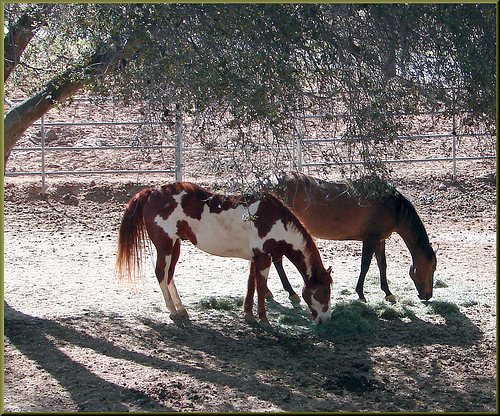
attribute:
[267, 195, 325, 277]
mane — Brown 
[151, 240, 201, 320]
legs — Back 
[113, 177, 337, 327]
horse — spotted , brown, white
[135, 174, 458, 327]
horse — brown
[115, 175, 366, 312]
horse — white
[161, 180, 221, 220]
spots — brown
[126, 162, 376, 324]
horse — spotted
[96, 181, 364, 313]
horse — spotted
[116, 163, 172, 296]
tail — brown, hairy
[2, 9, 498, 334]
tree — large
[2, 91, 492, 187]
fence — metal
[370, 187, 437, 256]
mane — dark colored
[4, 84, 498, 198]
fence — silver, metal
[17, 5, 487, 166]
leaves — green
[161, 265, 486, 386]
grass — green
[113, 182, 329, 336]
horse — brown, white, spotted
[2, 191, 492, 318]
ground — sandy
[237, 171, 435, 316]
horse — dark brown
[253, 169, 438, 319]
horse — brown, dark brown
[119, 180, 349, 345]
horse — brown, white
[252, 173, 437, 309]
horse — brown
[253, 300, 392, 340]
grass — clumps, green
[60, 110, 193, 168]
enslosure — metal, fence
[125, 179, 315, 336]
horse — white, brown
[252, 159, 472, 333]
horse — brown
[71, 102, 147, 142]
fence — metal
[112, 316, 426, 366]
grass — patch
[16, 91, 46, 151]
tree trunk — large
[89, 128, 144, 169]
dirt — patch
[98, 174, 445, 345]
horses — multicolored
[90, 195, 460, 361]
horses — multicolored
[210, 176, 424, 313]
horses — brown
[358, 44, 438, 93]
branch — tree